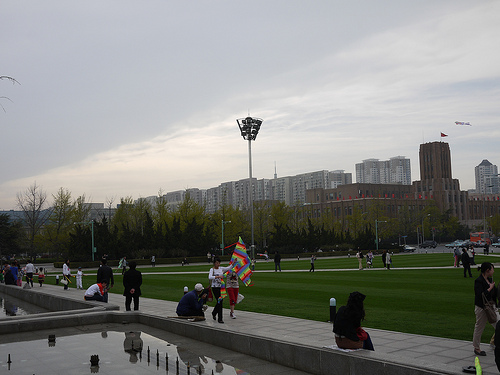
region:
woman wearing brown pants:
[471, 300, 491, 352]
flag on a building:
[436, 128, 451, 142]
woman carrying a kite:
[194, 245, 261, 310]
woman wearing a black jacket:
[469, 275, 495, 318]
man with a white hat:
[193, 281, 203, 291]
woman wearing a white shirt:
[58, 261, 73, 276]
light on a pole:
[236, 106, 262, 145]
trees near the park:
[72, 193, 241, 255]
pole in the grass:
[322, 293, 341, 325]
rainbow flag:
[225, 226, 263, 283]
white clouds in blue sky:
[371, 56, 423, 106]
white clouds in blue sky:
[295, 101, 339, 151]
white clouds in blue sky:
[138, 106, 182, 151]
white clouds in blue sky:
[37, 71, 92, 112]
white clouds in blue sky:
[50, 106, 138, 154]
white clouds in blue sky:
[134, 33, 176, 77]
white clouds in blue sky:
[51, 31, 85, 62]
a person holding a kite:
[209, 223, 282, 313]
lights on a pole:
[217, 95, 292, 208]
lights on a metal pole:
[229, 105, 286, 180]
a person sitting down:
[321, 260, 380, 365]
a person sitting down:
[164, 279, 206, 322]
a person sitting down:
[78, 278, 118, 324]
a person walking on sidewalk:
[111, 251, 163, 323]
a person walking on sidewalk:
[196, 248, 244, 327]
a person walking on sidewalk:
[454, 258, 496, 314]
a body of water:
[43, 308, 173, 373]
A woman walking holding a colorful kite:
[204, 237, 248, 326]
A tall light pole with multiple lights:
[236, 116, 262, 241]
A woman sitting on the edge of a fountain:
[326, 289, 375, 358]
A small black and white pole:
[323, 291, 337, 328]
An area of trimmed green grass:
[390, 280, 447, 324]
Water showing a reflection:
[141, 339, 169, 374]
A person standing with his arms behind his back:
[121, 256, 144, 310]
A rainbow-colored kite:
[228, 240, 252, 287]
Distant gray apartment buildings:
[186, 182, 250, 209]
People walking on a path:
[353, 248, 400, 270]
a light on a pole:
[215, 91, 368, 248]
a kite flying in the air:
[457, 113, 499, 136]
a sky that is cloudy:
[12, 3, 492, 153]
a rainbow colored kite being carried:
[221, 236, 267, 284]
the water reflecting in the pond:
[10, 328, 200, 372]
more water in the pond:
[3, 291, 36, 316]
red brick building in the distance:
[402, 121, 472, 225]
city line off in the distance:
[126, 143, 376, 209]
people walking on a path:
[273, 242, 404, 283]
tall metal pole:
[248, 140, 254, 265]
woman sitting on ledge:
[332, 290, 375, 350]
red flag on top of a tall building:
[420, 132, 452, 177]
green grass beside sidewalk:
[27, 266, 498, 338]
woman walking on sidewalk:
[472, 260, 499, 356]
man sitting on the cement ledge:
[174, 281, 209, 323]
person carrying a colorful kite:
[203, 232, 255, 322]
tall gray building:
[355, 155, 412, 183]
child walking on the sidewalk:
[69, 264, 84, 289]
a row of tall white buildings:
[173, 165, 345, 225]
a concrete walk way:
[250, 305, 324, 348]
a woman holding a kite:
[210, 235, 254, 283]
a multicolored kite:
[227, 234, 253, 286]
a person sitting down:
[87, 272, 114, 306]